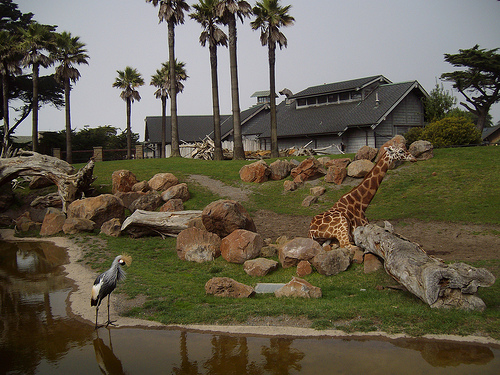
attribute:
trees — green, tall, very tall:
[6, 1, 291, 164]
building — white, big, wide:
[134, 72, 422, 152]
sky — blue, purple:
[5, 2, 498, 113]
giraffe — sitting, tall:
[296, 147, 420, 253]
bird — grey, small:
[84, 246, 140, 334]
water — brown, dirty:
[1, 245, 498, 374]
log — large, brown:
[7, 141, 104, 220]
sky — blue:
[36, 3, 494, 109]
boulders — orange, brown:
[232, 139, 404, 194]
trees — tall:
[165, 8, 280, 164]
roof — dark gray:
[183, 49, 451, 172]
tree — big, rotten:
[9, 145, 99, 217]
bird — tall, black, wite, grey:
[74, 245, 134, 326]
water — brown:
[45, 317, 378, 370]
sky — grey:
[322, 12, 440, 61]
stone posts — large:
[48, 139, 146, 157]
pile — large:
[184, 130, 225, 162]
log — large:
[355, 210, 493, 311]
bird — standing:
[86, 248, 133, 331]